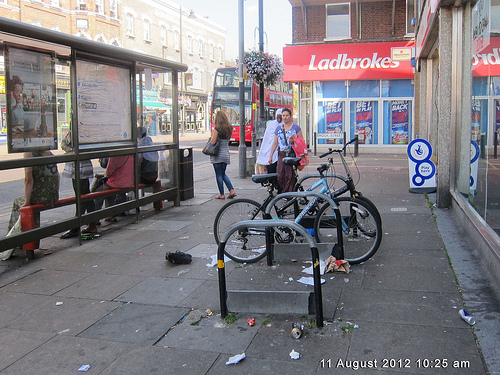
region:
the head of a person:
[277, 106, 297, 126]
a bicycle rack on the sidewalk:
[241, 184, 331, 319]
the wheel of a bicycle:
[311, 193, 384, 264]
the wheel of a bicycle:
[213, 198, 278, 267]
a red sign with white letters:
[294, 48, 413, 78]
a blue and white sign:
[409, 135, 439, 197]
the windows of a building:
[164, 18, 216, 58]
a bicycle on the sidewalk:
[214, 163, 401, 262]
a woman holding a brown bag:
[202, 111, 242, 196]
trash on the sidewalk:
[296, 251, 356, 291]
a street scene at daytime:
[11, 14, 485, 356]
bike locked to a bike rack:
[207, 177, 387, 262]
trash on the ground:
[294, 250, 356, 291]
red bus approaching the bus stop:
[212, 54, 293, 134]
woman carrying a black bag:
[201, 106, 240, 202]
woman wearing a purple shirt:
[277, 109, 302, 184]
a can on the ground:
[450, 302, 487, 333]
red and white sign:
[281, 47, 413, 77]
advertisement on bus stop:
[1, 41, 62, 153]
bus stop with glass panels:
[1, 30, 178, 211]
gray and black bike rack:
[211, 169, 361, 334]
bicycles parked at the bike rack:
[210, 163, 384, 258]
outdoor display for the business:
[399, 141, 439, 195]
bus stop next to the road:
[0, 17, 183, 266]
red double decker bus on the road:
[205, 68, 297, 150]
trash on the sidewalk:
[42, 189, 482, 361]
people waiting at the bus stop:
[10, 124, 171, 247]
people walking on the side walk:
[250, 104, 310, 204]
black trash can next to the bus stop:
[165, 141, 200, 206]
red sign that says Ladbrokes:
[279, 38, 416, 86]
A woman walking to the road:
[210, 101, 238, 203]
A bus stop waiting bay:
[19, 32, 181, 244]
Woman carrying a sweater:
[276, 108, 309, 197]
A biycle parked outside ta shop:
[220, 141, 385, 263]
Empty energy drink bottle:
[452, 296, 482, 333]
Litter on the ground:
[306, 243, 354, 291]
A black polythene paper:
[163, 244, 205, 276]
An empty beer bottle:
[290, 317, 308, 344]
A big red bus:
[213, 63, 290, 137]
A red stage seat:
[26, 186, 141, 253]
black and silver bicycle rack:
[211, 189, 348, 337]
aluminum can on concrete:
[285, 323, 307, 341]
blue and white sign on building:
[406, 138, 439, 193]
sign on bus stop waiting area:
[3, 36, 59, 156]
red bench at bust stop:
[14, 181, 146, 253]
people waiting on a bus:
[9, 127, 171, 242]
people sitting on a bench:
[5, 127, 165, 249]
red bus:
[207, 64, 295, 148]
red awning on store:
[281, 42, 422, 81]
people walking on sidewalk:
[201, 100, 308, 205]